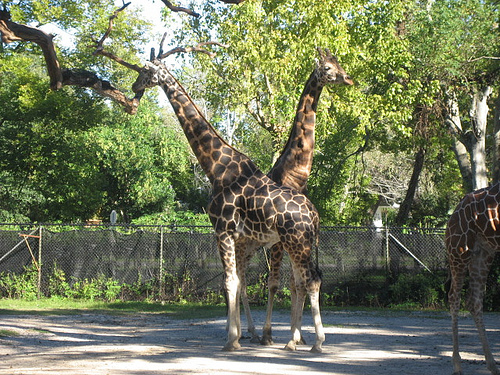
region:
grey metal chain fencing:
[330, 232, 377, 277]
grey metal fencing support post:
[320, 224, 386, 229]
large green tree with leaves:
[0, 115, 165, 197]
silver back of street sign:
[105, 208, 120, 226]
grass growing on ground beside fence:
[40, 298, 105, 311]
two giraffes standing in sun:
[129, 47, 374, 362]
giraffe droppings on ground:
[465, 353, 490, 369]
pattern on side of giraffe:
[243, 193, 285, 225]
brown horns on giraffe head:
[310, 42, 339, 63]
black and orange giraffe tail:
[311, 218, 323, 282]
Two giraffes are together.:
[95, 38, 387, 358]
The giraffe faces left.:
[102, 33, 246, 205]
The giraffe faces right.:
[248, 49, 370, 196]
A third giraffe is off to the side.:
[432, 114, 498, 371]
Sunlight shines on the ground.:
[0, 307, 437, 373]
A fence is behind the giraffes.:
[0, 201, 477, 311]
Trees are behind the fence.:
[0, 0, 495, 202]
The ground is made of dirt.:
[0, 290, 490, 373]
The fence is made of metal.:
[0, 209, 472, 314]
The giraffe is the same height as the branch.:
[100, 37, 361, 362]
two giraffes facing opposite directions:
[133, 30, 365, 373]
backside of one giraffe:
[448, 171, 498, 371]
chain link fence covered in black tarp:
[8, 208, 485, 304]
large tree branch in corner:
[8, 14, 197, 104]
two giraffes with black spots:
[133, 54, 357, 362]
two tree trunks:
[437, 69, 498, 196]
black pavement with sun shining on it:
[16, 311, 436, 373]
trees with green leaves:
[5, 17, 491, 216]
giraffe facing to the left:
[114, 46, 279, 331]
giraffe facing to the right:
[276, 39, 369, 187]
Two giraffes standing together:
[116, 21, 385, 356]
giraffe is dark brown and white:
[126, 55, 330, 340]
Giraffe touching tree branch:
[2, 14, 341, 354]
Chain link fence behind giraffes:
[13, 221, 492, 329]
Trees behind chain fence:
[1, 3, 482, 300]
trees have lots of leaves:
[8, 9, 493, 230]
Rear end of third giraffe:
[413, 148, 499, 350]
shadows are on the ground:
[9, 290, 499, 374]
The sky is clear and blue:
[18, 7, 255, 160]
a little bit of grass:
[5, 291, 461, 320]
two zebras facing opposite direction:
[126, 43, 365, 349]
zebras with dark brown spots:
[129, 53, 350, 345]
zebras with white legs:
[210, 277, 329, 354]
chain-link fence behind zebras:
[0, 225, 498, 314]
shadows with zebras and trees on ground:
[0, 305, 499, 374]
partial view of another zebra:
[448, 181, 497, 371]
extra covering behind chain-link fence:
[3, 228, 499, 304]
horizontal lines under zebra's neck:
[281, 160, 314, 195]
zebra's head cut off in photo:
[441, 152, 498, 373]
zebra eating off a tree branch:
[103, 37, 159, 113]